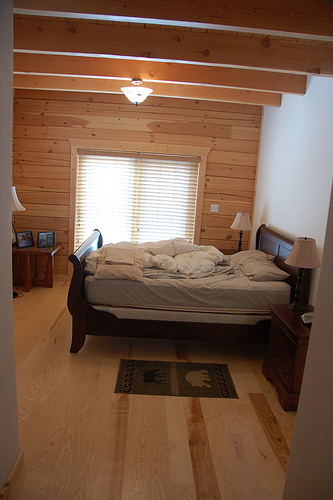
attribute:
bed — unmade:
[82, 221, 286, 331]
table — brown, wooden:
[12, 241, 62, 289]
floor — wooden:
[109, 401, 282, 492]